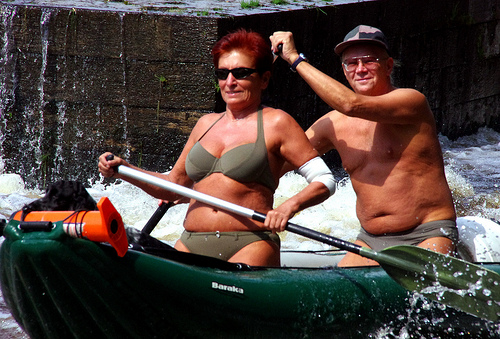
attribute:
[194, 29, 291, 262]
woman — old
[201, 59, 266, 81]
sunglasses — black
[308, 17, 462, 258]
man — bare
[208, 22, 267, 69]
red hair — short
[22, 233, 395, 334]
raft — green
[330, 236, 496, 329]
paddle — long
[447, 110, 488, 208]
water — rough, white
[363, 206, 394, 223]
belly button — large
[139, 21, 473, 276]
people — rowing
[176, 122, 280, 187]
bra — green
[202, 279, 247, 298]
baraka — white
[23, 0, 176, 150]
rock — gray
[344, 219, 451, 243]
briefs — green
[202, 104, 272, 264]
swimsuit — green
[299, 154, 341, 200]
elbow band — white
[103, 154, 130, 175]
handle — black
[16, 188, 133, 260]
equipment — orange